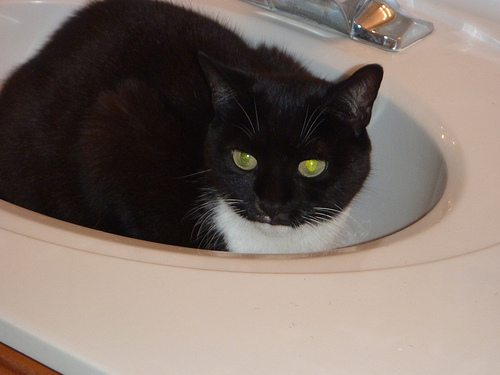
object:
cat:
[0, 0, 384, 252]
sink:
[0, 1, 463, 255]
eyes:
[232, 149, 259, 171]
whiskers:
[187, 189, 248, 251]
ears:
[195, 49, 252, 115]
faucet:
[251, 0, 436, 50]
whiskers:
[230, 93, 263, 139]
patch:
[208, 198, 351, 257]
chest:
[178, 195, 358, 255]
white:
[217, 200, 350, 254]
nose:
[256, 197, 290, 219]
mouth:
[245, 218, 306, 236]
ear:
[326, 63, 385, 128]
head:
[198, 54, 385, 235]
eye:
[298, 159, 328, 177]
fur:
[3, 1, 273, 246]